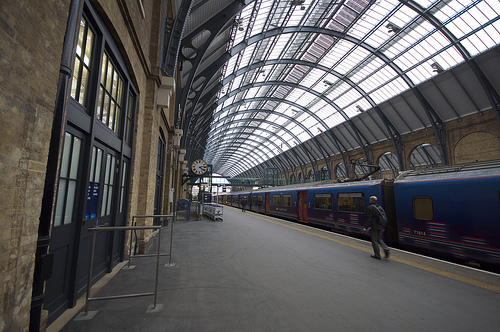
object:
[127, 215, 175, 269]
rails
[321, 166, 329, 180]
window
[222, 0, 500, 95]
window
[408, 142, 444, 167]
window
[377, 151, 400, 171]
window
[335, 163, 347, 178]
window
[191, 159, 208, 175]
clock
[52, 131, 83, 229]
window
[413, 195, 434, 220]
window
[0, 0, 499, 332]
building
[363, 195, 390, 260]
man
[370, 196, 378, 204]
head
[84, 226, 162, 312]
hand rail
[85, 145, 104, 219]
window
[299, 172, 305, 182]
window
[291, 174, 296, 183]
window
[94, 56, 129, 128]
window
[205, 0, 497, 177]
sky light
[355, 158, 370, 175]
window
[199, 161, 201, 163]
roman numerals